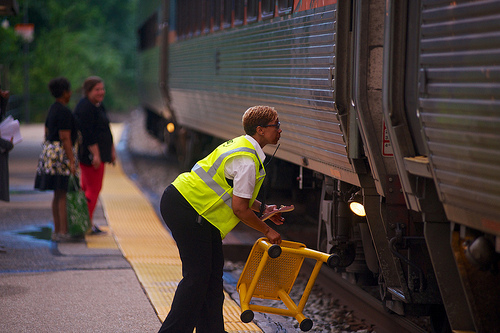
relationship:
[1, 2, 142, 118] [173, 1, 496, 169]
trees behind train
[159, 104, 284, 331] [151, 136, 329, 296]
person wearing vest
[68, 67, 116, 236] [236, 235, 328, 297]
woman holding stepstool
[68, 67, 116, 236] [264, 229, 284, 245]
woman has hand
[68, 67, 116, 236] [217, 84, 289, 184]
woman with hair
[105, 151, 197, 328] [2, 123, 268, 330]
line on platform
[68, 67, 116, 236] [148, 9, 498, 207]
woman inspect train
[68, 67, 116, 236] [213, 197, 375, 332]
woman holding stool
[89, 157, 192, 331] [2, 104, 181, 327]
stripe on platform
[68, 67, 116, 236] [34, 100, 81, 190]
woman wearing dress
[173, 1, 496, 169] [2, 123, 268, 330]
train stopped beside platform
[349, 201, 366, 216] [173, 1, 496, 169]
light on train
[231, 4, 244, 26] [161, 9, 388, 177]
window on train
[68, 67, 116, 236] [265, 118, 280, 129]
woman wearing eyeglasses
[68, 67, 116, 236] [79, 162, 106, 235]
woman wearing pants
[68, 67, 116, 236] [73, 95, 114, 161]
woman wearing sweater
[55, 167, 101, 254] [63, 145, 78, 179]
green bag in right hand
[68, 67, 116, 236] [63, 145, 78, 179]
woman has right hand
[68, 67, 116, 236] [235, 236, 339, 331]
woman with stool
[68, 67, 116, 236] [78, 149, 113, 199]
woman wearing red pant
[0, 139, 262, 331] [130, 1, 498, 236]
platform next to train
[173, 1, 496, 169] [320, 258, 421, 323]
train on tracks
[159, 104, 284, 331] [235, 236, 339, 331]
person holding stool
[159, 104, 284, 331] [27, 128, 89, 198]
person wearing dress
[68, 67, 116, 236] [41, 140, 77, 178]
woman wearing skirt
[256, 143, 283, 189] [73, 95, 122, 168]
walkie talkie in front of shirt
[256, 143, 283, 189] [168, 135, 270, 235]
walkie talkie in front of shirt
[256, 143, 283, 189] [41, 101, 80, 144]
walkie talkie in front of shirt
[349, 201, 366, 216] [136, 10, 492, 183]
light on bottom of train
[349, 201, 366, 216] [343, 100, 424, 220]
light near stairs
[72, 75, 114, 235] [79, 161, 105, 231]
lady wearing pants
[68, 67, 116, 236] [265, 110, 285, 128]
woman with glasses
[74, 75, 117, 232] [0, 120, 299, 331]
passenger at platform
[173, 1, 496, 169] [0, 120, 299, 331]
train at platform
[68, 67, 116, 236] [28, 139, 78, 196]
woman wearing skirt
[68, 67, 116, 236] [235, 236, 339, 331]
woman picking up stool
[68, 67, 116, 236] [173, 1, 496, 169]
woman beside train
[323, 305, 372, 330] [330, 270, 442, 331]
gravel beside tracks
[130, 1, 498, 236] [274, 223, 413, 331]
train on tracks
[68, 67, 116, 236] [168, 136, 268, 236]
woman wearing vest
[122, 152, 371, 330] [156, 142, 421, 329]
gravel around train tracks